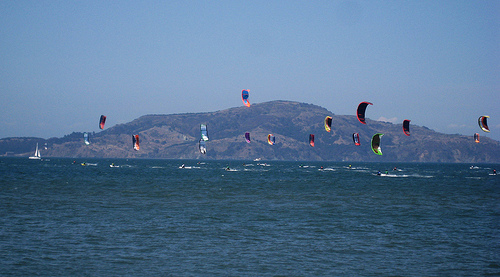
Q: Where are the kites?
A: The sky.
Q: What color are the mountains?
A: Brown.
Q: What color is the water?
A: Blue.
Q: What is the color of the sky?
A: Blue.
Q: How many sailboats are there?
A: One.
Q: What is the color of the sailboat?
A: White.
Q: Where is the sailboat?
A: The water.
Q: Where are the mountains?
A: The shore.